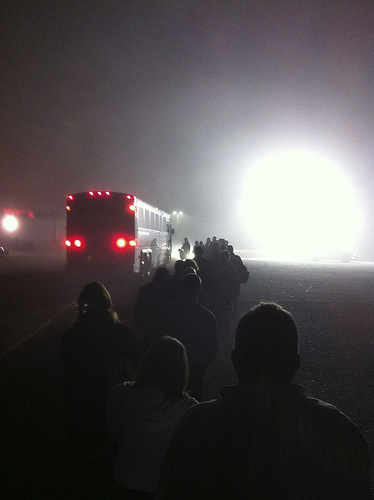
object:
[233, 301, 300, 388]
head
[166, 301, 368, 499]
person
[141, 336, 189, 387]
head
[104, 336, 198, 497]
person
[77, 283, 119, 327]
head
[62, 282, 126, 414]
person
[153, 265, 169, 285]
back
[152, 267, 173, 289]
head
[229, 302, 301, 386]
back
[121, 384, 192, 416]
hood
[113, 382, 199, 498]
jacket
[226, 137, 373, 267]
light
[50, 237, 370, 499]
group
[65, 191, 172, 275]
bus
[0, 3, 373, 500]
dark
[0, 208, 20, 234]
light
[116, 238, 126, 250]
light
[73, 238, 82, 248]
light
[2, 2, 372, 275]
night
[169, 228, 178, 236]
mirror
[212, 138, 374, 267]
building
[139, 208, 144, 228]
window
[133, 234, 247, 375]
line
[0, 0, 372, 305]
background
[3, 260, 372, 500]
ground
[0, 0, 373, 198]
sky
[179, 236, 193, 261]
person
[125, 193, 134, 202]
light